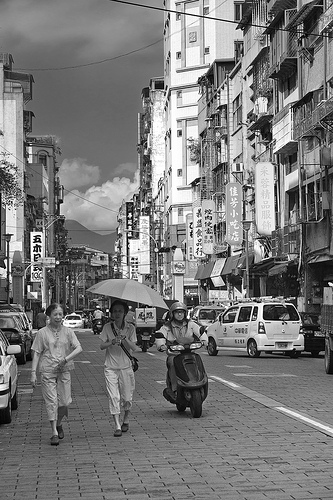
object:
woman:
[30, 302, 82, 446]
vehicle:
[0, 309, 34, 365]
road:
[0, 324, 333, 497]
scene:
[0, 0, 332, 499]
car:
[204, 303, 306, 357]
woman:
[99, 300, 137, 436]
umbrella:
[83, 276, 172, 344]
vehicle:
[0, 329, 21, 424]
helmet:
[169, 301, 190, 322]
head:
[170, 302, 185, 325]